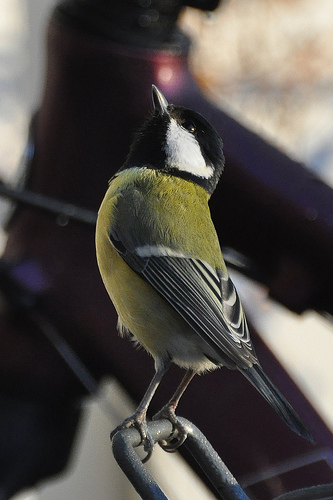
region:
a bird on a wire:
[96, 80, 311, 460]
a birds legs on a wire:
[102, 366, 195, 454]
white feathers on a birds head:
[156, 118, 204, 171]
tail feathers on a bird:
[229, 352, 327, 441]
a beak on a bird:
[145, 77, 173, 114]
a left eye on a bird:
[176, 116, 197, 127]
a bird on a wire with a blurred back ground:
[3, 5, 331, 495]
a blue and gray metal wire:
[106, 405, 249, 497]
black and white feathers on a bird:
[151, 269, 248, 351]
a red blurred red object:
[0, 1, 330, 81]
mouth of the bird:
[126, 72, 184, 115]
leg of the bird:
[124, 360, 198, 398]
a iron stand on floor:
[93, 390, 220, 470]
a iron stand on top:
[110, 379, 213, 466]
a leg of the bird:
[104, 399, 175, 465]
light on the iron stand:
[183, 414, 197, 436]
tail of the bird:
[223, 343, 320, 434]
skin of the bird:
[146, 197, 195, 233]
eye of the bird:
[180, 111, 197, 137]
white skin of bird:
[164, 122, 213, 173]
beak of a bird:
[150, 84, 167, 113]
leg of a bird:
[135, 358, 167, 418]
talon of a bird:
[110, 414, 152, 469]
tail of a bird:
[239, 363, 312, 442]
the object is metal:
[111, 419, 247, 498]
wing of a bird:
[101, 188, 250, 369]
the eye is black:
[186, 124, 194, 132]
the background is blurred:
[2, 1, 331, 498]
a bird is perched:
[97, 81, 314, 459]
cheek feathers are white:
[168, 116, 212, 178]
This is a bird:
[79, 80, 304, 476]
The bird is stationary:
[71, 73, 304, 455]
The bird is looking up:
[127, 77, 234, 179]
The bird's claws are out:
[113, 415, 195, 465]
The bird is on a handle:
[103, 387, 214, 471]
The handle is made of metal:
[112, 405, 244, 499]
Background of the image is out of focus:
[7, 8, 326, 475]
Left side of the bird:
[91, 82, 293, 455]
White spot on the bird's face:
[159, 112, 209, 176]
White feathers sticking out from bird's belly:
[114, 312, 148, 358]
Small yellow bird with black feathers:
[95, 83, 314, 464]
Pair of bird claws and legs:
[108, 362, 197, 462]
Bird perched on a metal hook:
[93, 82, 317, 498]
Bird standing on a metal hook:
[89, 81, 317, 498]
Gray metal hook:
[112, 413, 254, 497]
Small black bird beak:
[149, 80, 168, 117]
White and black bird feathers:
[107, 222, 258, 370]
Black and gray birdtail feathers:
[232, 358, 314, 446]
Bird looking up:
[89, 81, 314, 467]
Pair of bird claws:
[107, 405, 190, 466]